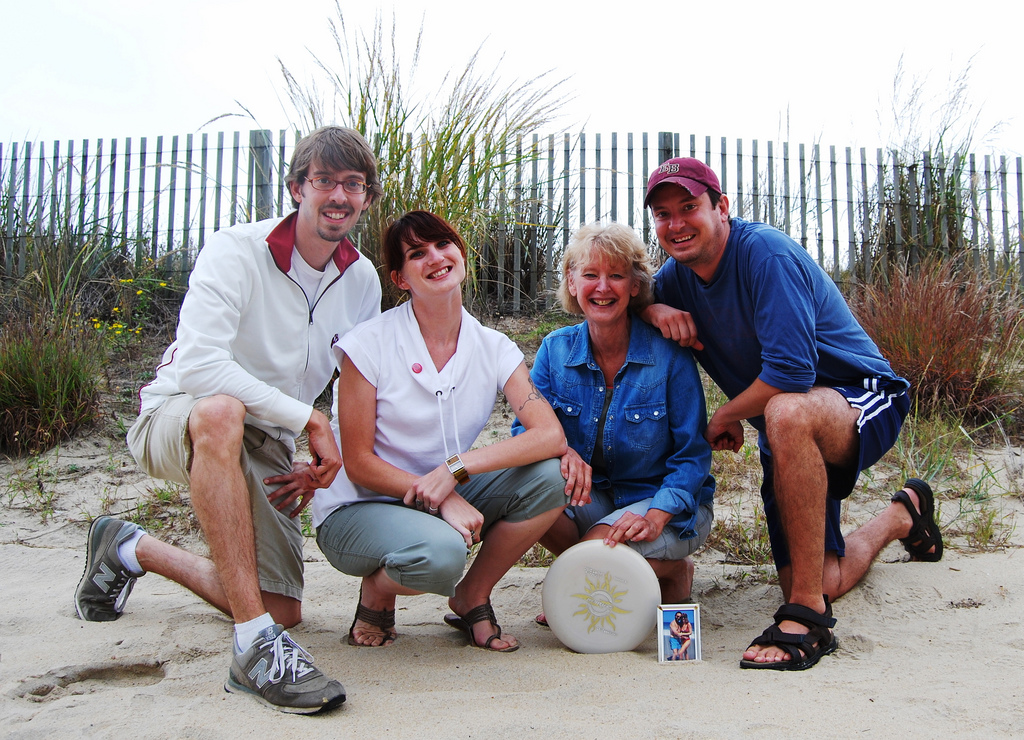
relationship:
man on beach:
[643, 157, 944, 672] [19, 379, 1013, 717]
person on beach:
[510, 221, 716, 627] [19, 379, 1013, 717]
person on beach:
[312, 211, 570, 653] [19, 379, 1013, 717]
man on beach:
[74, 125, 384, 715] [19, 379, 1013, 717]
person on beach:
[507, 208, 728, 647] [19, 379, 1013, 717]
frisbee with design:
[528, 534, 673, 662] [564, 562, 631, 638]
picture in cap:
[664, 614, 690, 654] [657, 603, 703, 663]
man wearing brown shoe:
[643, 157, 944, 672] [740, 594, 838, 671]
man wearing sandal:
[643, 157, 944, 672] [880, 467, 943, 565]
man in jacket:
[74, 125, 384, 715] [143, 211, 385, 451]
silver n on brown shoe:
[192, 606, 352, 713] [674, 582, 919, 671]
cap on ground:
[657, 603, 703, 663] [525, 649, 735, 732]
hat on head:
[643, 157, 722, 209] [622, 140, 731, 261]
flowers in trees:
[26, 204, 135, 408] [41, 189, 199, 380]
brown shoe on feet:
[740, 594, 838, 671] [741, 535, 839, 672]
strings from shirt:
[408, 358, 471, 469] [322, 274, 541, 560]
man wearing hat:
[639, 148, 860, 661] [635, 140, 709, 214]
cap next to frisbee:
[657, 603, 703, 663] [542, 515, 649, 656]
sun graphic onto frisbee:
[568, 544, 627, 625] [531, 513, 661, 673]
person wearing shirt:
[312, 211, 570, 653] [312, 298, 525, 529]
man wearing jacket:
[168, 112, 383, 594] [139, 209, 383, 451]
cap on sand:
[657, 603, 703, 663] [598, 632, 778, 721]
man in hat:
[643, 157, 944, 672] [617, 140, 732, 199]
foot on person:
[203, 610, 329, 729] [147, 60, 422, 605]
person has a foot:
[339, 202, 549, 661] [350, 580, 392, 647]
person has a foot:
[312, 211, 570, 653] [442, 584, 518, 656]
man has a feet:
[643, 157, 944, 672] [744, 595, 832, 663]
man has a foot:
[643, 157, 944, 672] [898, 480, 940, 552]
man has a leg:
[74, 125, 384, 715] [186, 404, 346, 718]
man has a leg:
[643, 157, 944, 672] [764, 398, 834, 666]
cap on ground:
[657, 603, 703, 663] [574, 668, 749, 736]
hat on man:
[641, 150, 721, 203] [643, 157, 944, 672]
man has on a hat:
[643, 157, 944, 672] [641, 150, 721, 203]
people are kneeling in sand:
[186, 104, 919, 690] [460, 675, 631, 734]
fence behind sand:
[553, 134, 646, 199] [494, 655, 657, 718]